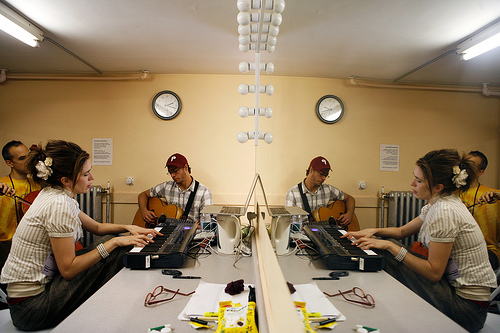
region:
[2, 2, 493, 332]
three people reflected in a large mirror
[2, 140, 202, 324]
woman playing a keyboard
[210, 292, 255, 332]
a bag of cough drops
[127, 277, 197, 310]
pair of glasses on counter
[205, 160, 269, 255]
laptop computer on white, handled object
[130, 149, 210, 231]
man playing a guitar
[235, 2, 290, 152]
light bulbs along top and side of mirror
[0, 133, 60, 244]
man holding a bow to a musical instrument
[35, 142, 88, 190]
floral designs on woman's hair accessories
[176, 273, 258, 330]
papers on counter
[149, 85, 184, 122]
The clock on the left.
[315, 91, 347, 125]
The clock in the reflection of the mirror.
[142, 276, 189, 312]
The red glasses on the table.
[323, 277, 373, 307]
The red glasses in the reflection of the mirror.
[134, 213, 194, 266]
The keyboard the girl is playing.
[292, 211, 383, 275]
The keyboard in the reflection of the mirror.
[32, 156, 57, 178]
The flowers in the girl's hair.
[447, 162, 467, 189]
The flowers in the girl's hair in the reflection of the mirror.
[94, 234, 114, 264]
The bracelet the girl is wearing.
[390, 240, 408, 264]
The bracelet the girl is wearing in the reflection of the mirror.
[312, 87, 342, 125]
A clock on the wall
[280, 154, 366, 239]
A man playing a guitar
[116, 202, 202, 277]
A keyboard on a table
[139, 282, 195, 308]
A pair of glasses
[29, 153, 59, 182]
Flowers in a woman's hair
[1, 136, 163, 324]
A woman playing the keyboard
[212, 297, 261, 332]
A bag of cough drops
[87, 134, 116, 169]
Paper attached to the wall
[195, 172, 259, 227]
A laptop computer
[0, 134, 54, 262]
A man playing the cello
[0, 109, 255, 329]
people playing music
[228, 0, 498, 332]
people is reflected on a big mirror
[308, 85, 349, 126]
clock is reflected on a mirror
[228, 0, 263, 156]
white lights on top a mirror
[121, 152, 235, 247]
man is playing the guitar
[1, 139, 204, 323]
woman is playing the piano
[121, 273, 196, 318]
a pair of glasses on a counter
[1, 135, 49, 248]
man holds a bow of violin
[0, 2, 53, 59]
light in the ceiling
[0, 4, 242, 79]
ceiling is white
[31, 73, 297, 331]
the mirror is clear